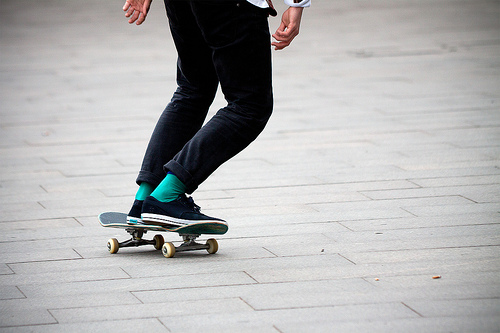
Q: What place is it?
A: It is a walkway.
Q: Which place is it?
A: It is a walkway.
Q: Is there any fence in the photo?
A: No, there are no fences.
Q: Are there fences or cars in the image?
A: No, there are no fences or cars.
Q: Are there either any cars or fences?
A: No, there are no fences or cars.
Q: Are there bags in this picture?
A: No, there are no bags.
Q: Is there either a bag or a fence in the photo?
A: No, there are no bags or fences.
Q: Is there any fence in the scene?
A: No, there are no fences.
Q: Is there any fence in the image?
A: No, there are no fences.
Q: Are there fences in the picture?
A: No, there are no fences.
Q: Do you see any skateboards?
A: Yes, there is a skateboard.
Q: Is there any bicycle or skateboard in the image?
A: Yes, there is a skateboard.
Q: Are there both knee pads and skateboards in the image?
A: No, there is a skateboard but no knee pads.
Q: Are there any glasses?
A: No, there are no glasses.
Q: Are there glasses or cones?
A: No, there are no glasses or cones.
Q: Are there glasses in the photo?
A: No, there are no glasses.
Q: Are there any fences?
A: No, there are no fences.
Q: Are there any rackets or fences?
A: No, there are no fences or rackets.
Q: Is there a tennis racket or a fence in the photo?
A: No, there are no fences or rackets.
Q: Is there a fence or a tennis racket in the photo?
A: No, there are no fences or rackets.